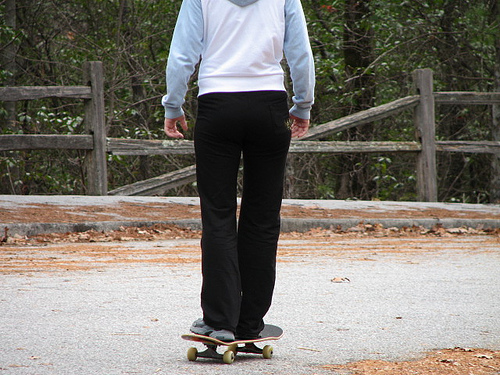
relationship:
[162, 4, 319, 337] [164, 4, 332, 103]
person wearing shirt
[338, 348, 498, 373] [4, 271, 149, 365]
dead brush on ground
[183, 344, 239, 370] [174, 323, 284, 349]
wheels on skateboard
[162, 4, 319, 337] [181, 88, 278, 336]
person in pants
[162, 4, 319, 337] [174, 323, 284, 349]
person riding skateboard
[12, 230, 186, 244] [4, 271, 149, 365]
leaves on ground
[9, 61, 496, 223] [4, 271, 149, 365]
fence on side of ground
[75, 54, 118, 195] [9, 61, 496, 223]
post on fence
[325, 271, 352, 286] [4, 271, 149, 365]
dead leaf in middle of ground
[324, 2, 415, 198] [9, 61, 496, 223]
dead tree behind fence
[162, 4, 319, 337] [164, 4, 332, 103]
person in shirt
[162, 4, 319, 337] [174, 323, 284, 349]
person on skateboard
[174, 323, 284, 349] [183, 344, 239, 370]
skateboard with wheels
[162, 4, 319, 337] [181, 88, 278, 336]
person has pants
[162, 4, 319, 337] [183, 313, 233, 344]
person with shoe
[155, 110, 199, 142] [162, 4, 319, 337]
hand of person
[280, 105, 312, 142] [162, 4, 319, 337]
hand of person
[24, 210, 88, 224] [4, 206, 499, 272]
clay on ground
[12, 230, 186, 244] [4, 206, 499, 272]
leaves on ground